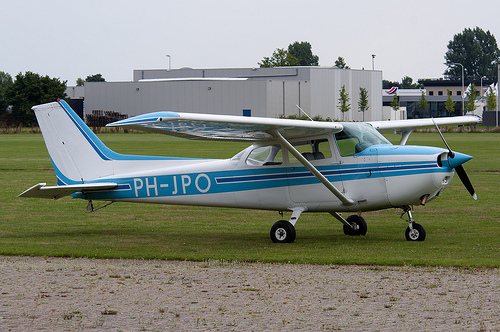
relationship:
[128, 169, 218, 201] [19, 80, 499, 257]
white letters on plane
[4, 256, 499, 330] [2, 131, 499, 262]
dirt next to grass field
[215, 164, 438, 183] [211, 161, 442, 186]
stripe on plane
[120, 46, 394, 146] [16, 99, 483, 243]
building behind airplane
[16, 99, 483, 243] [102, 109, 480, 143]
airplane has wing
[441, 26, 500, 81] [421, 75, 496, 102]
leaves behind building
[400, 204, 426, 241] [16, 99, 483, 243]
landing gear in front of airplane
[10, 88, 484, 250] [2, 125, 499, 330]
airplane on ground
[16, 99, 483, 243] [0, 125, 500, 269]
airplane parked in grass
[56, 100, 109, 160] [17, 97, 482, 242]
stripe painted on airplane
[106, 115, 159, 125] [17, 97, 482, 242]
stripe painted on airplane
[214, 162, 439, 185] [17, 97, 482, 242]
stripe painted on airplane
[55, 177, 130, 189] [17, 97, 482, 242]
stripe painted on airplane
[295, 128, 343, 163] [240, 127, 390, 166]
seats in cockpit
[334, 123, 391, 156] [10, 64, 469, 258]
windshield on plane.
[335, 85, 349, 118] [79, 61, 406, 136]
trees near building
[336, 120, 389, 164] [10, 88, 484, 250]
windshield on airplane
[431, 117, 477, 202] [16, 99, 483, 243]
propeller on airplane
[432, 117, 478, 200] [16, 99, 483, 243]
propeller of airplane